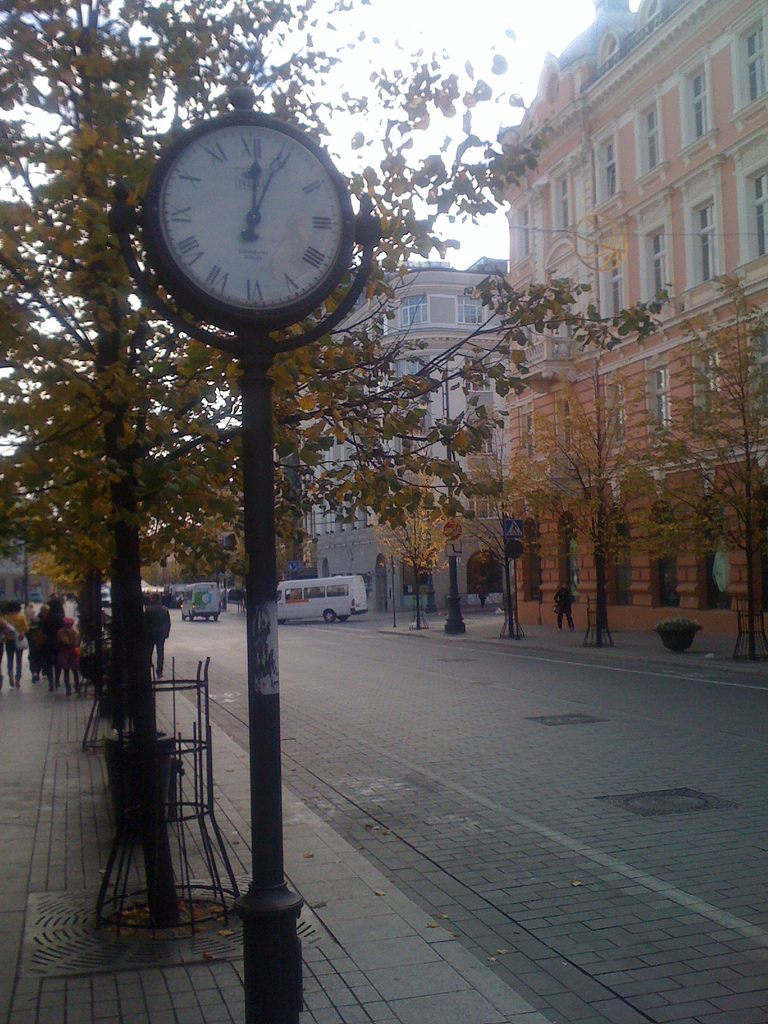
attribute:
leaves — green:
[579, 296, 661, 350]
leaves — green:
[67, 42, 163, 101]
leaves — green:
[71, 41, 128, 92]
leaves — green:
[159, 467, 228, 519]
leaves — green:
[396, 64, 483, 125]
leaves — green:
[331, 460, 420, 520]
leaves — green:
[44, 516, 115, 566]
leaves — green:
[151, 14, 221, 78]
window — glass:
[679, 189, 728, 288]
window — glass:
[633, 216, 679, 309]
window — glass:
[572, 142, 641, 186]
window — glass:
[680, 83, 722, 141]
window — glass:
[626, 218, 676, 295]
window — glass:
[576, 137, 630, 200]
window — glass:
[526, 177, 587, 243]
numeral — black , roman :
[238, 135, 263, 164]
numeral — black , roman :
[227, 126, 271, 167]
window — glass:
[632, 208, 682, 314]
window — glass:
[587, 227, 634, 324]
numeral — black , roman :
[226, 123, 276, 169]